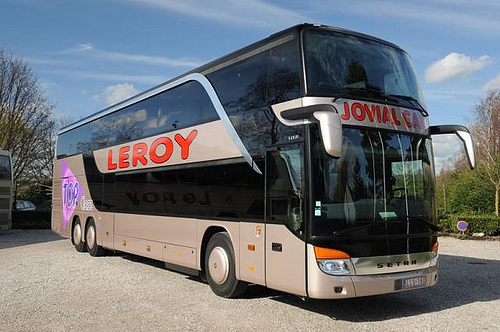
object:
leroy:
[107, 130, 198, 170]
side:
[50, 23, 306, 298]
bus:
[50, 22, 477, 303]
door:
[264, 142, 308, 298]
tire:
[205, 231, 248, 298]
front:
[299, 23, 444, 302]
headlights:
[316, 260, 350, 276]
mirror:
[279, 104, 342, 160]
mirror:
[429, 124, 479, 170]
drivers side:
[375, 35, 443, 294]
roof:
[53, 22, 430, 161]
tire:
[71, 214, 88, 253]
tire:
[84, 215, 107, 257]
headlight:
[430, 250, 438, 265]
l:
[107, 149, 117, 169]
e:
[118, 146, 130, 169]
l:
[391, 108, 401, 125]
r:
[132, 143, 148, 167]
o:
[149, 136, 174, 164]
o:
[351, 102, 367, 121]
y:
[174, 130, 198, 159]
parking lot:
[2, 191, 500, 331]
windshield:
[309, 122, 437, 237]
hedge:
[437, 210, 499, 240]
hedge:
[11, 208, 53, 229]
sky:
[0, 0, 499, 177]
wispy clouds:
[21, 39, 178, 79]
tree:
[0, 46, 57, 212]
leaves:
[33, 112, 49, 133]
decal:
[59, 158, 86, 236]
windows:
[54, 25, 437, 258]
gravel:
[0, 228, 499, 331]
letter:
[341, 102, 350, 120]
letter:
[364, 103, 375, 121]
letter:
[402, 111, 411, 128]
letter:
[376, 105, 383, 123]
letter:
[382, 105, 392, 124]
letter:
[412, 112, 420, 127]